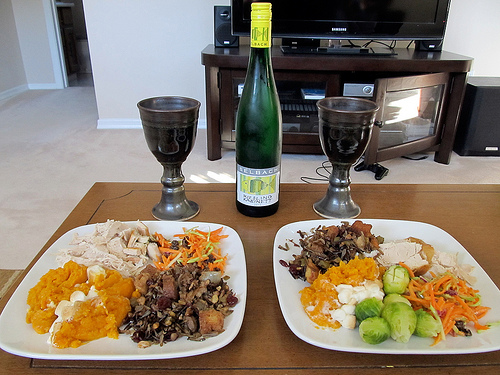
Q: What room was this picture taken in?
A: A living room.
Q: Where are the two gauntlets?
A: On the table.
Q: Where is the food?
A: On the plates.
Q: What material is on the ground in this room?
A: Carpet.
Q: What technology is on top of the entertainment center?
A: A television and speakers.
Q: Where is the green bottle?
A: On the table.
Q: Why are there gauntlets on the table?
A: For the drink.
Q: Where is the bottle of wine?
A: On the table.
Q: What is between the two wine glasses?
A: A bottle of wine.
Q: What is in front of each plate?
A: A wine glass.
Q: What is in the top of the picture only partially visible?
A: A tv.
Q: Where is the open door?
A: On the tv stand.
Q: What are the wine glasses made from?
A: Metal.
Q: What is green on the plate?
A: Brussels sprouts.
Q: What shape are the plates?
A: Square.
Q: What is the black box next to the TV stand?
A: A speaker.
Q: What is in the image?
A: Food.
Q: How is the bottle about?
A: Wine.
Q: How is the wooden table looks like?
A: Wood.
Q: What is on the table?
A: Pewter goblet.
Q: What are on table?
A: Two dinner plates.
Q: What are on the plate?
A: Mashed sweet potatoes.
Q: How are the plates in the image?
A: White.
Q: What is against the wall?
A: Entertainment center.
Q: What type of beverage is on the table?
A: Wine.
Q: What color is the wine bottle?
A: Green.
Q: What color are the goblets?
A: Black.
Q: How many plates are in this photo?
A: 2.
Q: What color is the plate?
A: White.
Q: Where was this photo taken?
A: In a living room.